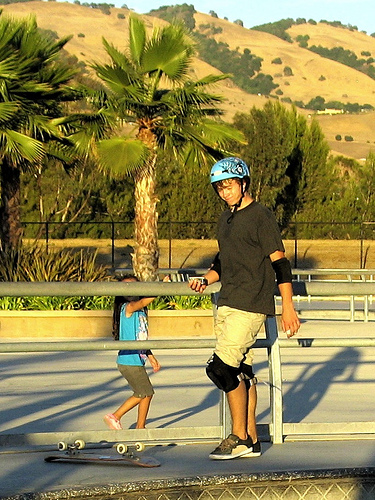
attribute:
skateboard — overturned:
[41, 437, 161, 468]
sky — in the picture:
[48, 0, 374, 36]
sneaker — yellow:
[207, 432, 253, 458]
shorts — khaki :
[208, 302, 268, 366]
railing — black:
[20, 220, 374, 283]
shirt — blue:
[87, 298, 190, 382]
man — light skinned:
[187, 157, 299, 459]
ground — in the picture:
[299, 101, 315, 130]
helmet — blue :
[188, 133, 266, 215]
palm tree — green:
[60, 10, 245, 285]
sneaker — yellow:
[211, 434, 254, 461]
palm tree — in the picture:
[72, 6, 247, 291]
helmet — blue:
[208, 155, 249, 189]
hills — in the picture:
[1, 4, 373, 112]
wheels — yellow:
[108, 439, 153, 460]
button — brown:
[138, 388, 149, 394]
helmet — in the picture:
[206, 154, 251, 184]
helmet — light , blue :
[207, 153, 252, 185]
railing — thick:
[5, 273, 374, 357]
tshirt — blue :
[108, 308, 164, 381]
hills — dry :
[33, 12, 360, 269]